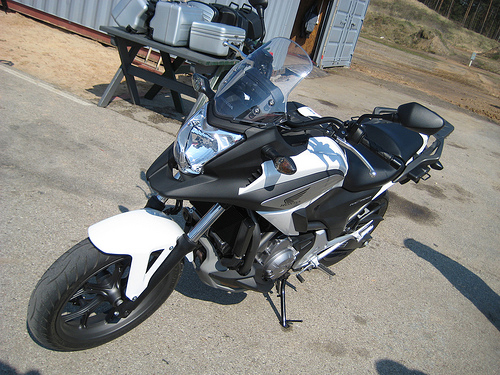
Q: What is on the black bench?
A: Luggage.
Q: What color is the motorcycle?
A: Black and white.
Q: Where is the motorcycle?
A: On the street.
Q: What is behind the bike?
A: A picnic table.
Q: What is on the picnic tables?
A: Metal luggage.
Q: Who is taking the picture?
A: A photographer.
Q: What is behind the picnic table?
A: A shed.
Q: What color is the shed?
A: Grey.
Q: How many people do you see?
A: None.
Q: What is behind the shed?
A: A road.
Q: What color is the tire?
A: Black.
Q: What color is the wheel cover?
A: White.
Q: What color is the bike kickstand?
A: Black.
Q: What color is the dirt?
A: Brown.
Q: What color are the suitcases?
A: Gray.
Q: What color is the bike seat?
A: Black.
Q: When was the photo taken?
A: Daytime.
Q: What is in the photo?
A: Motorcycle.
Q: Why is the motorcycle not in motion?
A: It is parked.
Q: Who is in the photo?
A: No one.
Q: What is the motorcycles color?
A: Black and white.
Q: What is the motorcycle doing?
A: Motionless.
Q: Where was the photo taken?
A: On a street.